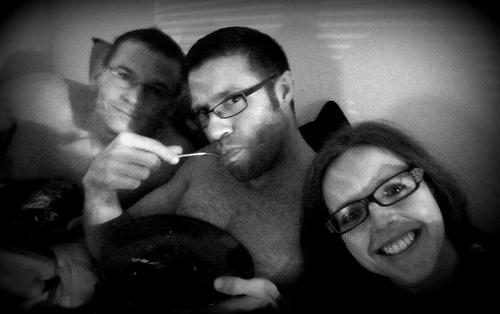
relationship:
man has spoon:
[82, 26, 319, 311] [171, 151, 219, 157]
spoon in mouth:
[171, 151, 219, 157] [218, 146, 241, 161]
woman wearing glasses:
[300, 121, 498, 313] [325, 160, 424, 236]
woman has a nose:
[300, 121, 498, 313] [367, 200, 396, 233]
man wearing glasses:
[82, 26, 319, 311] [185, 72, 281, 131]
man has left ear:
[82, 26, 319, 311] [277, 71, 294, 104]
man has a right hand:
[82, 26, 319, 311] [84, 132, 183, 190]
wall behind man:
[0, 0, 495, 234] [82, 26, 319, 311]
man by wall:
[1, 26, 197, 250] [0, 0, 495, 234]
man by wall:
[82, 26, 319, 311] [0, 0, 495, 234]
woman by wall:
[300, 121, 498, 313] [0, 0, 495, 234]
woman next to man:
[300, 121, 498, 313] [82, 26, 319, 311]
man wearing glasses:
[1, 26, 197, 250] [106, 64, 170, 107]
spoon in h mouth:
[171, 151, 219, 157] [218, 146, 241, 161]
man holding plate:
[82, 26, 319, 311] [95, 214, 255, 309]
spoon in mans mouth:
[171, 151, 219, 157] [218, 146, 241, 161]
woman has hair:
[300, 121, 498, 313] [303, 119, 472, 284]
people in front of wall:
[0, 29, 496, 310] [0, 0, 495, 234]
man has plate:
[82, 26, 319, 311] [95, 214, 255, 309]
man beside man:
[82, 26, 319, 311] [1, 26, 197, 250]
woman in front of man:
[300, 121, 498, 313] [82, 26, 319, 311]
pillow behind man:
[89, 37, 349, 153] [82, 26, 319, 311]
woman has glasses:
[300, 121, 498, 313] [325, 160, 424, 236]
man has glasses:
[82, 26, 319, 311] [185, 72, 281, 131]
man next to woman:
[82, 26, 319, 311] [300, 121, 498, 313]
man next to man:
[82, 26, 319, 311] [1, 26, 197, 250]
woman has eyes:
[300, 121, 498, 313] [341, 185, 401, 225]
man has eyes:
[82, 26, 319, 311] [199, 96, 239, 119]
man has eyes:
[1, 26, 197, 250] [120, 73, 164, 98]